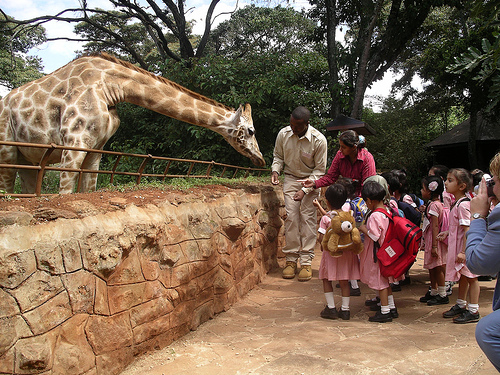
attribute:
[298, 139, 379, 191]
shirt — red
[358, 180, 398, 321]
girl — little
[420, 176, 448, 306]
girl — little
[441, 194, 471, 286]
dress — pink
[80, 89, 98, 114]
spot — small, brown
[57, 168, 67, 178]
spot — brown, small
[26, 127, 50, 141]
spot — brown, small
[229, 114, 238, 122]
spot — brown, small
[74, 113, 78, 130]
spot — brown, small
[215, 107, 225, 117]
spot — brown, small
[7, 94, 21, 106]
spot — brown, small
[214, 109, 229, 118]
spot — brown, small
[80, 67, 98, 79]
spot — brown, small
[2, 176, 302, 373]
wall — brown, rock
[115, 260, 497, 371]
path — rock, brown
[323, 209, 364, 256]
teddy bear — brown, plush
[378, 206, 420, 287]
backpack — red, large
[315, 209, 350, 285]
dress — pink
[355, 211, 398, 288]
dress — pink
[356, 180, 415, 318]
girl — little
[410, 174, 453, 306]
girl — little, pink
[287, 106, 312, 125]
hair — black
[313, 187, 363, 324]
girl — little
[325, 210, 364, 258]
backpack — teddy bear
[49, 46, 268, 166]
giraffe — tan, brown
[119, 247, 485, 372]
ground — cement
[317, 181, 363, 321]
girl — little